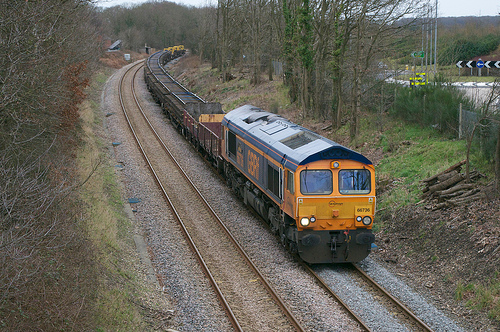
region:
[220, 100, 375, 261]
an orange train engine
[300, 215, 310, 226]
the train engines headlight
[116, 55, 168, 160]
the railroad train tracks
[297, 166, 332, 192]
the train front windshield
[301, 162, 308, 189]
the trains windshield wiper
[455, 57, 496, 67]
a road sign on the highway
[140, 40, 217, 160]
cargo train cars behind the train engine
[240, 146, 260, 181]
the trains identification number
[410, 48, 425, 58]
green street signs on the highway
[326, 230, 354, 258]
train car coupling attachment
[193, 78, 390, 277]
An orange train car.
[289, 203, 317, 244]
a head light on a train.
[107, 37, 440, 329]
Train tracks on a countryside.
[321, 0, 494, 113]
a building with a parking lot.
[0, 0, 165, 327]
A lush green countryside.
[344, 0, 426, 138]
a tall green leaf filled tree.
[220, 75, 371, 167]
The top of an orange train.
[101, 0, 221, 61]
A forest filled with green trees.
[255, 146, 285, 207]
a window on a train.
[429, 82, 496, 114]
a paved area.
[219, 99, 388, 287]
This is a train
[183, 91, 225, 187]
This is a train carrier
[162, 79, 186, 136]
This is a train carrier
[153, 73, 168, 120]
This is a train carrier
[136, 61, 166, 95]
This is a train carrier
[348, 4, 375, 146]
This is a tree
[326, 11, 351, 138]
This is a tree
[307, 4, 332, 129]
This is a tree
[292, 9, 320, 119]
This is a tree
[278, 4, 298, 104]
This is a tree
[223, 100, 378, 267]
a yellow orange and blue train engine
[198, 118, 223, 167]
a brown coal car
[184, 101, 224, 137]
a brown coal car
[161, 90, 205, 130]
a flatbed train car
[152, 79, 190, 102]
a flatbed train car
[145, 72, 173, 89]
a flatbed train car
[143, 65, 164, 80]
a flatbed train car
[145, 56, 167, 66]
a flatbed train car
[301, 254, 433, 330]
a set of train tracks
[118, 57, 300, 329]
a set of train tracks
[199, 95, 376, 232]
Yellow and purple caboose of train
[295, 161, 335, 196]
Left window of caboose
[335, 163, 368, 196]
Right window of caboose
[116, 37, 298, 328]
Tracks for trains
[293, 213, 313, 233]
Left back light of caboose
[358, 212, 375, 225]
Right light of caboose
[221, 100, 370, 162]
Top of yellow and purple caboose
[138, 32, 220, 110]
train cars going around the bend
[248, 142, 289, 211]
Side window of yellow and purple caboose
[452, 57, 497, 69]
Black and white directional arrows